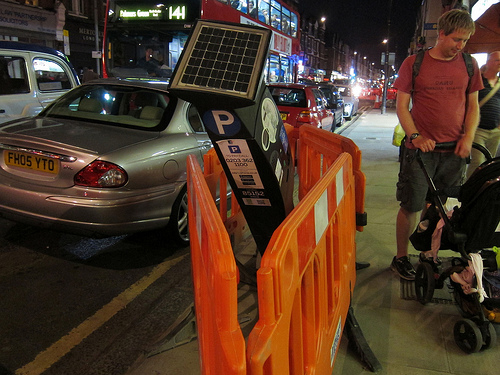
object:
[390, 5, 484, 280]
man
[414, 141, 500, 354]
stroller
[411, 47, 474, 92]
backpack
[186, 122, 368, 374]
barricades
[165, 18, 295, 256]
meter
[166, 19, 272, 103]
solar panel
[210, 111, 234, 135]
p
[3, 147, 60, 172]
plate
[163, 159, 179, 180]
gas tank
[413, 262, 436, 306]
wheel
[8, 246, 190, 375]
line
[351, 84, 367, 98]
lights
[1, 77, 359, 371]
street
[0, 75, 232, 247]
car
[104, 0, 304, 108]
bus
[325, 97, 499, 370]
sidewalk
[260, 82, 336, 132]
car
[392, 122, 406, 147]
bag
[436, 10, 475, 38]
hair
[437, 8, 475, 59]
head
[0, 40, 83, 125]
car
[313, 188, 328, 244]
square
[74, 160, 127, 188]
lights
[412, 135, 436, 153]
hand